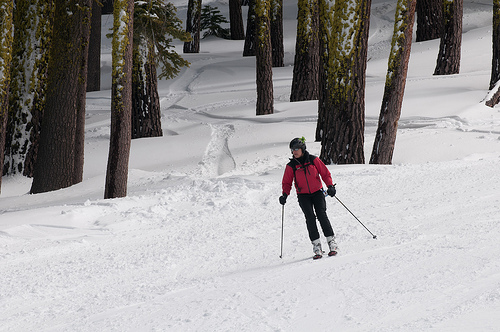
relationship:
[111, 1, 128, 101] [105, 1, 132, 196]
moss growing on tree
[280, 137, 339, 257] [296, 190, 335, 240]
person wearing pants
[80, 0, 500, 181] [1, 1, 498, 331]
snow trail on top of ground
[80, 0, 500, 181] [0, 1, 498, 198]
snow trail through trees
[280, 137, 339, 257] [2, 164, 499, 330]
person on top of main trail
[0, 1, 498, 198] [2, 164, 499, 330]
trees next to main trail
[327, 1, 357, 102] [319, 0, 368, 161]
moss growing on tree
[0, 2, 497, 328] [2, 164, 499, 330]
snow on top of main trail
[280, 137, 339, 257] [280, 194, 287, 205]
person has right hand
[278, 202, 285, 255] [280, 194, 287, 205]
ski pole held by right hand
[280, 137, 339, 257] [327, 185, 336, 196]
person has left hand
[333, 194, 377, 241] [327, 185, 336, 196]
ski pole held in left hand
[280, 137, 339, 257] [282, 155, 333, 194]
person wearing jacket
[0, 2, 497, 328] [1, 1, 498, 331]
snow on top of ground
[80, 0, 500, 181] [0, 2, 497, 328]
snow trail through snow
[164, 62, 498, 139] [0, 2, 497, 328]
snow trail through snow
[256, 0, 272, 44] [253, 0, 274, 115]
moss on surface of tree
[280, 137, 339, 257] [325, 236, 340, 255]
person wearing boot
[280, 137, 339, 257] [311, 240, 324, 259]
person wearing boot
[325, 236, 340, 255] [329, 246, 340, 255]
boot on top of foot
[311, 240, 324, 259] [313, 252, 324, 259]
boot on top of foot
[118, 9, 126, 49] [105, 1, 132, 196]
snow stuck to tree